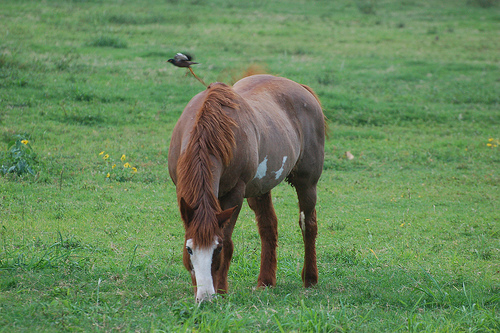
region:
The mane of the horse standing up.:
[185, 77, 225, 241]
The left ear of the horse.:
[172, 195, 193, 220]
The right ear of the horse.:
[218, 198, 237, 229]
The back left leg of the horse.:
[246, 189, 286, 289]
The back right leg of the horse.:
[297, 170, 326, 294]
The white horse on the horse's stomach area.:
[254, 147, 289, 189]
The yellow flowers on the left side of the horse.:
[14, 126, 151, 188]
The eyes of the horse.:
[178, 245, 226, 259]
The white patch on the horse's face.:
[182, 225, 228, 302]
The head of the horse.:
[165, 206, 244, 311]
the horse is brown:
[165, 64, 357, 311]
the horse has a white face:
[148, 64, 339, 329]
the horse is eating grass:
[166, 64, 344, 329]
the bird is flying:
[154, 32, 219, 90]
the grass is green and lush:
[330, 55, 458, 304]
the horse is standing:
[145, 66, 393, 305]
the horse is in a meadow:
[25, 16, 488, 329]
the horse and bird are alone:
[25, 23, 482, 331]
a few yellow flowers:
[14, 132, 139, 190]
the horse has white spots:
[171, 71, 337, 304]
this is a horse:
[137, 65, 337, 306]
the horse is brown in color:
[157, 80, 329, 313]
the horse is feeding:
[165, 262, 248, 325]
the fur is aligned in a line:
[181, 104, 236, 179]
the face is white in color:
[196, 251, 212, 296]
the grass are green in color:
[372, 258, 449, 331]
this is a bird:
[157, 44, 202, 73]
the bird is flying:
[166, 47, 199, 69]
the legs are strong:
[252, 185, 327, 284]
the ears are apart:
[169, 200, 241, 228]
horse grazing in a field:
[155, 71, 349, 312]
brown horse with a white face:
[165, 198, 233, 308]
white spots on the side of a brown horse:
[245, 145, 297, 192]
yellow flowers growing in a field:
[7, 127, 157, 185]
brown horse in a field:
[102, 44, 376, 314]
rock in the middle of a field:
[160, 42, 201, 73]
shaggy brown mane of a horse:
[181, 74, 235, 241]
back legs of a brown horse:
[247, 191, 328, 296]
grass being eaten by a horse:
[171, 294, 256, 324]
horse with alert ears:
[167, 190, 245, 315]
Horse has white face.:
[183, 232, 233, 317]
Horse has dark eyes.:
[179, 238, 253, 277]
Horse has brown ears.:
[174, 191, 297, 250]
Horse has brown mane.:
[168, 99, 228, 253]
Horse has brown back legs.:
[258, 214, 371, 283]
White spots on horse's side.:
[251, 156, 328, 178]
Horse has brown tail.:
[234, 56, 349, 123]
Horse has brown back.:
[223, 70, 320, 152]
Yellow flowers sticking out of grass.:
[18, 150, 177, 234]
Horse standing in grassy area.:
[134, 212, 374, 328]